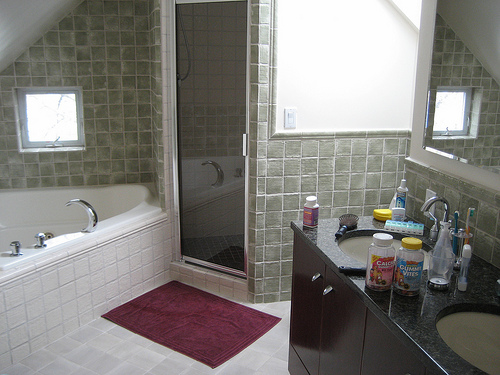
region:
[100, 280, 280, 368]
red rug in front of the shower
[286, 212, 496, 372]
black cabinet sitting against the wall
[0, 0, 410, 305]
gray and white tile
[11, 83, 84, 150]
window in the tiled wall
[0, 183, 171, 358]
white tub in the corner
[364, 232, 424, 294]
two plastic bottles sitting next to each other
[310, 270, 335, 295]
knobs on the black cabinet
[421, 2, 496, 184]
mirror hanging on the wall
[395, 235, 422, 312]
jar with a yellow top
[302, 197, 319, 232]
white plastic bottle with a red label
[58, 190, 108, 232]
a large tub faucet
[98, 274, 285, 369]
a maroon bath rug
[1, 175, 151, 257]
part of a white tub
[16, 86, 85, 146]
a small window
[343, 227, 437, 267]
a small white sink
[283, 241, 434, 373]
part of a bathroom cabinet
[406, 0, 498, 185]
part of a mirror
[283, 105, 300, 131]
a white wall outlet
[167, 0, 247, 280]
a long shower door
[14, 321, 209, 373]
part of a bathroom floor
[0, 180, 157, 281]
A bath in the bathroom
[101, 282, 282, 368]
A rug near the shower door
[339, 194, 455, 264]
A sink on the counter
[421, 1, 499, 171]
A mirror above the counter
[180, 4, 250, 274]
A door to the shower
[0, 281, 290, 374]
The floor of the bathroom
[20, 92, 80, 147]
A window above the bath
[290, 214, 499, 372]
A counter in the bathroom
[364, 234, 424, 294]
Two bottles of vitamins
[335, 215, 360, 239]
A hair brush on the counter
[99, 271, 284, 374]
Bath mat on bathroom floor.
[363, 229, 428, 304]
Two bottles of vitamins sitting on vanity.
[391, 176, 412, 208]
Tube of toothpaste sitting on vanity.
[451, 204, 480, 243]
Toothbrushes sitting on vanity.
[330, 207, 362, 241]
Hair brush lying on vanity.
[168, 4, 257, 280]
Glass door over shower stall.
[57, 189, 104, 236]
Curved faucet over bathtub.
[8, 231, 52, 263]
Hot and cold water controls on bathtub.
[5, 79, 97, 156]
Window on bathroom wall.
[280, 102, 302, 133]
Light switch mounted on wall.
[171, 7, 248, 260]
a door on the shower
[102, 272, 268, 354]
a rug on the floor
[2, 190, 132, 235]
a bath tub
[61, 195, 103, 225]
a faucet on the tub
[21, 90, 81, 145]
a window on the wall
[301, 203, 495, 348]
the counter in the bathroom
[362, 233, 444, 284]
bottles on the counter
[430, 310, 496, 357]
the sink on the counter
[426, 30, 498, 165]
the mirror behind the sink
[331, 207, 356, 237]
a brush on the counter